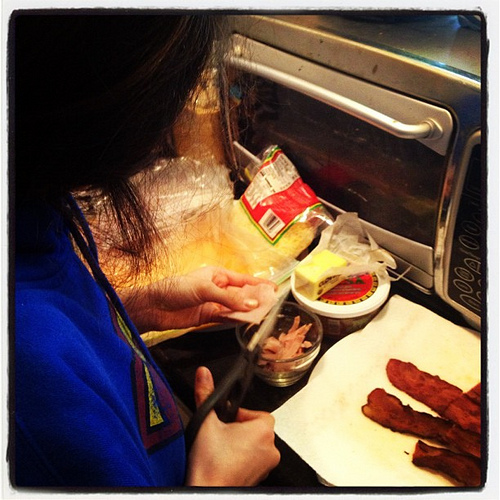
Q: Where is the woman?
A: In a kitchen.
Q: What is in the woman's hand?
A: A pair of Scissors.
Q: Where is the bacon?
A: On the countertop.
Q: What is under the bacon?
A: Paper towel.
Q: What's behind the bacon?
A: The toaster oven panel.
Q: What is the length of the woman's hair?
A: Long.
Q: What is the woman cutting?
A: Cheese.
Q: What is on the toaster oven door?
A: A handle.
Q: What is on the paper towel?
A: Bacon.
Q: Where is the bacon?
A: On a paper towel.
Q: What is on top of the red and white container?
A: Butter.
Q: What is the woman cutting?
A: Ham.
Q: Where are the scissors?
A: In the woman's right hand.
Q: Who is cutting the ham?
A: The woman in a blue shirt.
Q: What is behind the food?
A: A silver microwave.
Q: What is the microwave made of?
A: Stainless steel.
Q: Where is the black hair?
A: On the woman's head.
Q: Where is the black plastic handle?
A: On the scissors.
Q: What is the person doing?
A: Cutting meat.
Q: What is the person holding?
A: A pair of scissors with a black handle.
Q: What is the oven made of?
A: Metal.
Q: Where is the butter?
A: In the white wrapper.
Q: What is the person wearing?
A: A blue shirt with a red and yellow emblem.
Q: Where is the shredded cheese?
A: In a bag to the left of the butter.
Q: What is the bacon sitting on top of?
A: A white paper towel.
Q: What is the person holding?
A: Scissors with a black handle.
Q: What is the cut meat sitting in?
A: A small glass container.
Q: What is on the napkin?
A: Bacon.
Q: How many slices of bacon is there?
A: Three.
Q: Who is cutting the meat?
A: Lady.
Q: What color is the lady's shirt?
A: Blue.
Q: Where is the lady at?
A: Kitchen.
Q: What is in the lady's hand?
A: Scissors.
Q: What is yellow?
A: Butter.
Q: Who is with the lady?
A: No one.